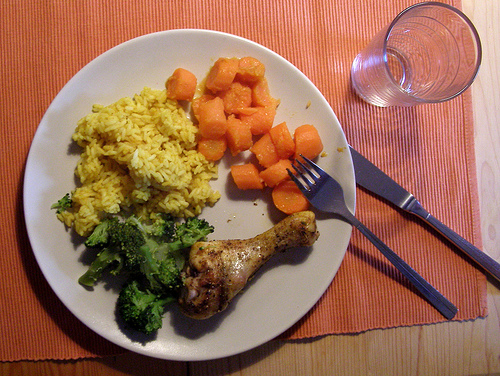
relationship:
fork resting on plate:
[289, 161, 462, 320] [23, 31, 355, 364]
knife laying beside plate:
[354, 145, 499, 285] [23, 31, 355, 364]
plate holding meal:
[23, 31, 355, 364] [60, 59, 321, 335]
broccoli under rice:
[55, 197, 76, 212] [61, 88, 218, 233]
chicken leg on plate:
[180, 213, 318, 320] [23, 31, 355, 364]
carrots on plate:
[167, 57, 322, 211] [23, 31, 355, 364]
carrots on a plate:
[167, 57, 322, 211] [23, 31, 355, 364]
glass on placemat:
[353, 0, 480, 110] [1, 2, 488, 359]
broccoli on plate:
[83, 218, 211, 335] [23, 31, 355, 364]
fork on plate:
[289, 161, 462, 320] [23, 31, 355, 364]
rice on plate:
[61, 88, 218, 233] [23, 31, 355, 364]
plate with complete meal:
[23, 31, 355, 364] [60, 59, 321, 335]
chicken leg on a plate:
[180, 213, 318, 320] [23, 31, 355, 364]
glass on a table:
[353, 0, 480, 110] [0, 1, 499, 374]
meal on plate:
[60, 59, 321, 335] [23, 31, 355, 364]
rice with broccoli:
[61, 88, 218, 233] [83, 218, 211, 335]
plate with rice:
[23, 31, 355, 364] [61, 88, 218, 233]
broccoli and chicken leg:
[83, 218, 211, 335] [180, 213, 318, 320]